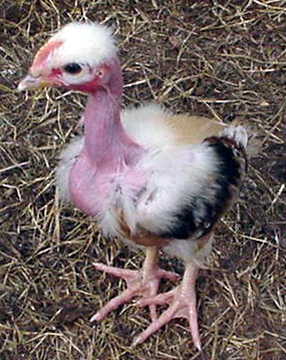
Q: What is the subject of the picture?
A: Baby turkey.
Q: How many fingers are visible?
A: 7.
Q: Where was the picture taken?
A: At the turkey farm.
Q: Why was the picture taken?
A: To show a cute little bird.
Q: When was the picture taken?
A: During daytime.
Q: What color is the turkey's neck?
A: Pink.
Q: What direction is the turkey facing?
A: To the left.